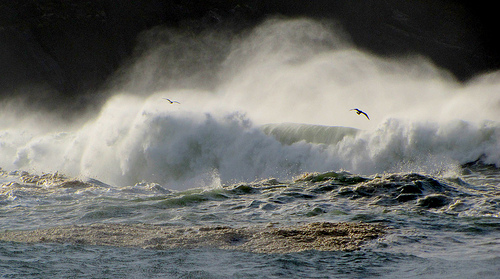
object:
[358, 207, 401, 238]
ground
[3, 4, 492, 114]
rock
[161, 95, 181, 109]
seagull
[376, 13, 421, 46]
white clouds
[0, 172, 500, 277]
light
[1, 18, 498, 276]
water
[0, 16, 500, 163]
clouds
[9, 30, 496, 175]
splash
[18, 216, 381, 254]
rocks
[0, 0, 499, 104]
sky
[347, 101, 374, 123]
bird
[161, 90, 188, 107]
bird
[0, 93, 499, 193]
wave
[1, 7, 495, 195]
spray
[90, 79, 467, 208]
splash